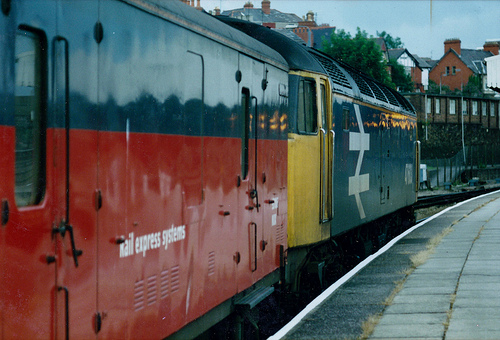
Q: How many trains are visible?
A: One.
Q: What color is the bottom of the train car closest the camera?
A: Red.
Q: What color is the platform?
A: Gray.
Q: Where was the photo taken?
A: Train station.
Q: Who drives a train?
A: Conductor.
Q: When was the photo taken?
A: Daytime.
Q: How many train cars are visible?
A: Two.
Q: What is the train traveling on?
A: Tracks.